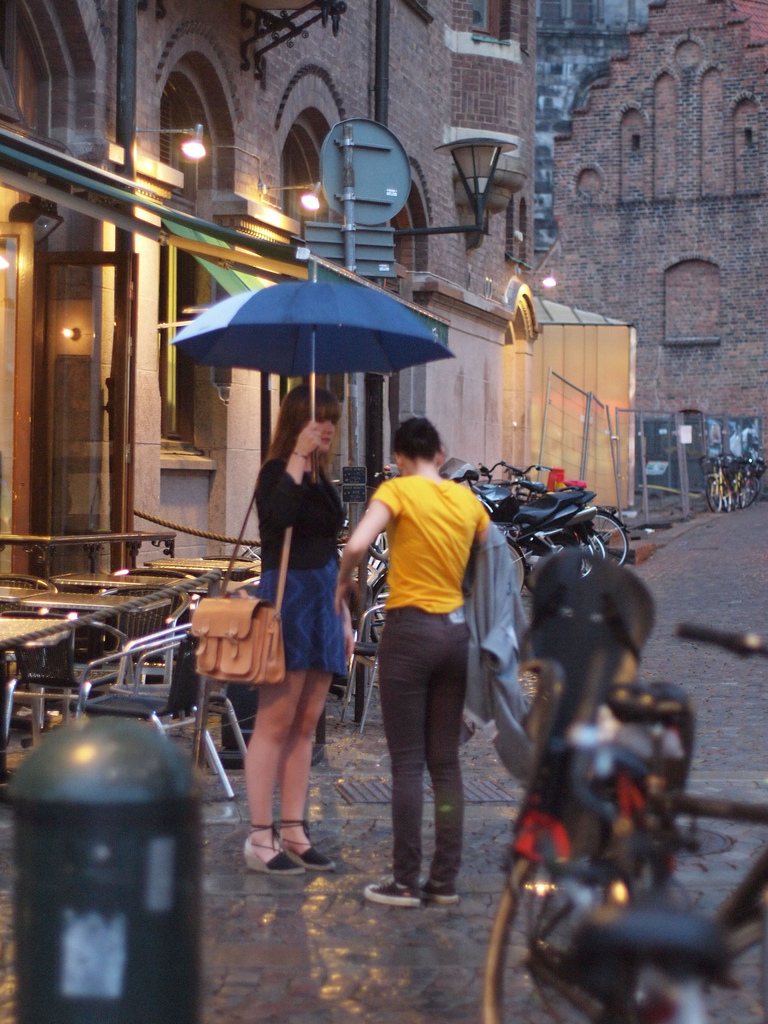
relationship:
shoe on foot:
[363, 880, 417, 906] [361, 874, 431, 907]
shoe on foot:
[214, 799, 365, 853] [214, 799, 365, 853]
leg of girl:
[254, 716, 365, 860] [233, 375, 353, 884]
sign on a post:
[280, 139, 459, 279] [280, 139, 459, 279]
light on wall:
[15, 310, 113, 388] [15, 310, 113, 388]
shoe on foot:
[240, 829, 309, 880] [245, 801, 378, 877]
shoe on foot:
[381, 825, 486, 917] [381, 825, 486, 917]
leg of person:
[368, 698, 442, 880] [368, 417, 493, 879]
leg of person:
[420, 703, 490, 882] [341, 437, 498, 838]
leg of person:
[214, 683, 312, 840] [214, 382, 312, 840]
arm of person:
[337, 501, 420, 582] [337, 501, 420, 582]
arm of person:
[249, 450, 358, 577] [249, 450, 358, 577]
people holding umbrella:
[327, 403, 535, 926] [192, 261, 505, 853]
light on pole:
[409, 130, 487, 241] [409, 130, 487, 241]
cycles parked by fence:
[677, 450, 762, 524] [576, 378, 762, 525]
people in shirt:
[327, 403, 535, 926] [313, 470, 552, 742]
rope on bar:
[23, 564, 262, 684] [23, 564, 262, 684]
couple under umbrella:
[197, 264, 484, 775] [197, 264, 484, 775]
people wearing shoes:
[327, 403, 535, 926] [322, 832, 504, 1003]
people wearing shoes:
[327, 403, 535, 926] [368, 788, 530, 886]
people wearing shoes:
[327, 403, 535, 926] [326, 430, 556, 930]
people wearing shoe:
[327, 403, 535, 926] [360, 875, 424, 914]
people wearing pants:
[327, 403, 535, 926] [361, 433, 475, 900]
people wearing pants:
[327, 403, 535, 926] [368, 600, 484, 888]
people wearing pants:
[327, 403, 535, 926] [363, 601, 479, 878]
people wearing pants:
[327, 403, 535, 926] [373, 593, 490, 882]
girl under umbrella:
[238, 395, 349, 881] [159, 251, 477, 404]